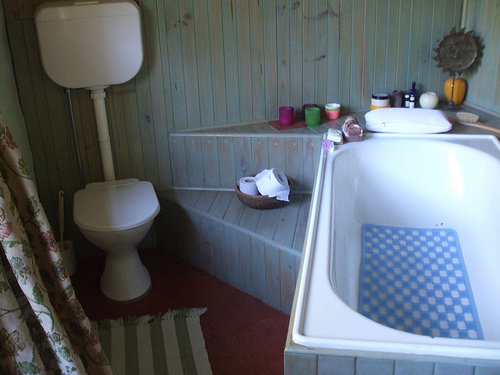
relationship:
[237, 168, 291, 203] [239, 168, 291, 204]
rolls on toilet paper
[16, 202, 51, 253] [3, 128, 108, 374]
flower pattered curtain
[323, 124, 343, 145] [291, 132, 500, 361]
soap on edge of bathtub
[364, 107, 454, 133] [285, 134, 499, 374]
pillow next to tube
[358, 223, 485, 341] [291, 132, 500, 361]
bath mat in a bathtub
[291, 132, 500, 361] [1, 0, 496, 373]
bathtub in a bathroom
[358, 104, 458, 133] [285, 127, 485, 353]
pillow by a bathtub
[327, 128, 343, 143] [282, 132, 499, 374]
soap by a bathtub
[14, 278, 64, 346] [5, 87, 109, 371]
part of a curtain